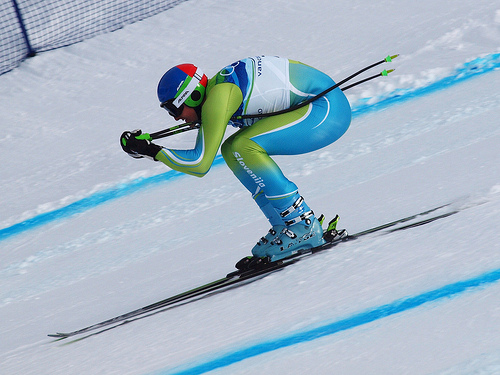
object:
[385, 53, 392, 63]
stick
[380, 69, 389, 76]
stick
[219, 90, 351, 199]
blue pants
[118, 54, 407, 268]
he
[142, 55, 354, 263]
costume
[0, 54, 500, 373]
lines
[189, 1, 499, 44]
snow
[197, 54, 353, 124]
shirt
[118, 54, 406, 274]
competition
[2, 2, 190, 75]
fence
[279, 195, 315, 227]
white snaps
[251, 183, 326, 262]
boots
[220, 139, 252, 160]
knees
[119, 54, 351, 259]
lady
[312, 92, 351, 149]
butt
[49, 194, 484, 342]
board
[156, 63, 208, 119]
helmet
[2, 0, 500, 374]
not shown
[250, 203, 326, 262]
shoes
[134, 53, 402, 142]
poles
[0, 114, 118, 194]
floor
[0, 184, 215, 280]
snow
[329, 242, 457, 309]
snow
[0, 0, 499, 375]
course